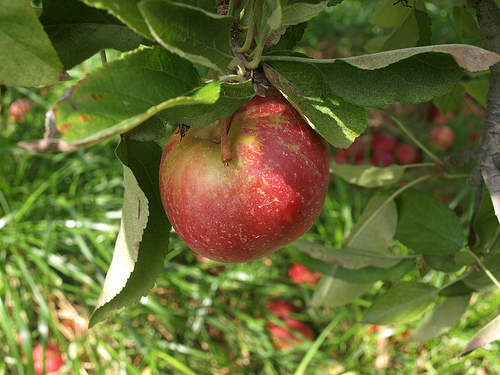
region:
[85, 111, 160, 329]
a green tree leaf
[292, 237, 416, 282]
a green tree leaf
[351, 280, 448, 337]
a green tree leaf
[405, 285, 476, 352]
a green tree leaf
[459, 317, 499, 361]
a green tree leaf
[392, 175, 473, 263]
a green tree leaf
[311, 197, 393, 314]
a green tree leaf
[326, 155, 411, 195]
a green tree leaf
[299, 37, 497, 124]
a green tree leaf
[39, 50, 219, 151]
a green tree leaf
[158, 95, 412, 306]
the apple is red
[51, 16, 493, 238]
the leaves are green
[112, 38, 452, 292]
the apple is attached to the leaves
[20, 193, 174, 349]
the grass is green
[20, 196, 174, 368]
the sun is shining on the grass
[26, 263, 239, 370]
the grass is covering the apples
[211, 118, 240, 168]
the stem on the apple is brown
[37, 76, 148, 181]
the leave is discolored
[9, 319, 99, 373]
red fruit buried in green grass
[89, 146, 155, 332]
hanging green leaf turned inside out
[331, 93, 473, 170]
a cluster of fruit laying on ground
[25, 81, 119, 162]
green leaf spotted with orange/brown specks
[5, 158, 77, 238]
grassy green area with fruit round about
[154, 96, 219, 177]
red and yellow fruit on a stem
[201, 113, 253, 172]
brown stem holding red/yellow frut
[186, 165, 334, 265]
white specks decked out on red round fruit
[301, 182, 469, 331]
cluster of leaves turned inside out and face up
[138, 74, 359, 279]
red and yellow speckled apple hanging from fruit tree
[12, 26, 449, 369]
an apple tree with fallen apples below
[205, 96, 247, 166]
a brown apple stem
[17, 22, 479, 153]
leaves on an apple tree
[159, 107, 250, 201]
a green spot on an apple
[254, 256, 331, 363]
fallen apples on the ground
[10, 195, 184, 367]
grass below an apple tree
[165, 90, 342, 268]
a red apple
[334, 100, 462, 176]
a bunch of red apples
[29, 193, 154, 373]
sun on green grass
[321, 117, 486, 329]
leaves in the shade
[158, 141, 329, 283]
The apple is red.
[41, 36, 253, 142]
The leaves are green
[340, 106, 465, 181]
Apples are in the background.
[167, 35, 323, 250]
The apple is hanging of the branch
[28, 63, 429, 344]
The tree is full of apples.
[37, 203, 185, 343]
The long grass grows beneath.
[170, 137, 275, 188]
Apple have some green on it.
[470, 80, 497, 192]
The branch is brown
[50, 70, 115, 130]
The leaf have some brown spots.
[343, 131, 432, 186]
A bundle of apples on one branch